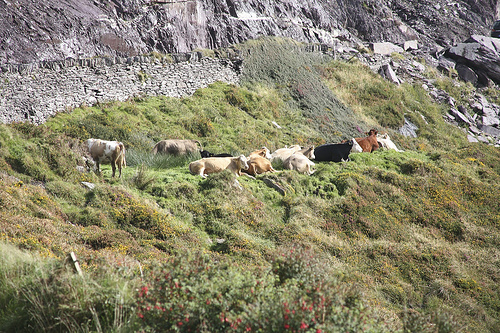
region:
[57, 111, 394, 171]
A group of cows are outside.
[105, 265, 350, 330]
Red flowers on a bush.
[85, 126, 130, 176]
A brown and white cow.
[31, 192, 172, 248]
Yellow flowers on a hillside.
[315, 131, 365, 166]
A black cow with a white head.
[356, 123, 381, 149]
The cow is brown.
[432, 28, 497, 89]
A cluster of large rocks.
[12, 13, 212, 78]
The hillside is rocky.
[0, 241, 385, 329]
Some bushes in the foreground.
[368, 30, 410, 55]
A white rock on the hillside.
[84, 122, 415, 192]
cows on a hill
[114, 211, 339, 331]
red flowers on the bushes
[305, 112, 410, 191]
black and white cow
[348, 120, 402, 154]
brown cow on the hill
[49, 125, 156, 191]
tan and white cow eating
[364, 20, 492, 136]
rocks on the hill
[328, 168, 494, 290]
flowers on the bushes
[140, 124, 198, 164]
tan cow eating food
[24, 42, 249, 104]
rock wall near the hill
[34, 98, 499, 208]
several cows on the hill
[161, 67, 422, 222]
the cows are visible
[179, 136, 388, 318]
the cows are visible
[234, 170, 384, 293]
the cows are visible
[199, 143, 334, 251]
the cows are visible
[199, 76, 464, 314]
the cows are visible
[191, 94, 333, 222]
the cows are visible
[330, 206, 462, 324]
the grass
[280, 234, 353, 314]
the grass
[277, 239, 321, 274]
the grass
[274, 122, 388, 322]
the grass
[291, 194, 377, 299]
the grass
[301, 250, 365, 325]
the grass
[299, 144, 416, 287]
the grass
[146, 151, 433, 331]
the grass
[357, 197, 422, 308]
the grass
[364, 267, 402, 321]
the grass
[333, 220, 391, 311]
the grass